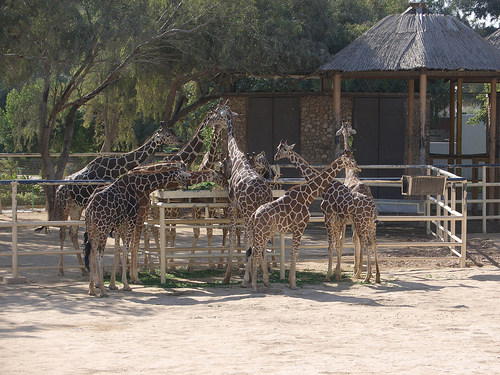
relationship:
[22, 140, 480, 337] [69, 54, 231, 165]
floor has plants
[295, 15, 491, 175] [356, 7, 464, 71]
house has roof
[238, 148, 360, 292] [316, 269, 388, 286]
giraffe has feet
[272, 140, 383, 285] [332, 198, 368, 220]
giraffe has spots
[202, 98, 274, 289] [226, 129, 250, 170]
giraffe has neck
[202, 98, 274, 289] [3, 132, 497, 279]
giraffe near fence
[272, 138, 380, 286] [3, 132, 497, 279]
giraffe near fence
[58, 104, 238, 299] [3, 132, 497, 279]
giraffe near fence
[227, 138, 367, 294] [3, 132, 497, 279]
giraffe near fence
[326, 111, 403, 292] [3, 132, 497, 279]
giraffe near fence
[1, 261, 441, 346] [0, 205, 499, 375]
shadows on floor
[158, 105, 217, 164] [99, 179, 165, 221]
mane of giraffe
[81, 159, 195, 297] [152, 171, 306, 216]
giraffe drinking water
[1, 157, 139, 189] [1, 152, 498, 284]
paint on fence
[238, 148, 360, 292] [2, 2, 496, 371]
giraffe at zoo